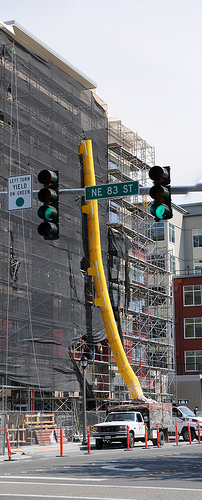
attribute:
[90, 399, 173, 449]
truck — parked, white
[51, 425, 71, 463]
traffic post — orange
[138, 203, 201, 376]
building — white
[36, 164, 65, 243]
traffic signal — black, metal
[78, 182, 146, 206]
street sign — green, white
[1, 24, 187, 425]
building — large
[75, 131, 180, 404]
tube — yellow, large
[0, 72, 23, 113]
person — working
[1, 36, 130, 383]
mesh — black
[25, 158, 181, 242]
trafficlights — green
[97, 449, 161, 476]
arrow — white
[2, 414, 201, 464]
construction poles — orange, white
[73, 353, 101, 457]
light post — grey, black